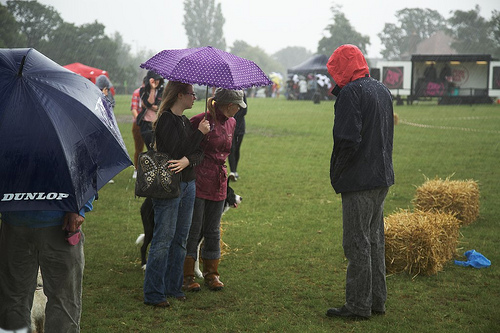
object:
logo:
[1, 191, 67, 202]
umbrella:
[0, 47, 133, 217]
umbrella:
[140, 46, 275, 132]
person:
[326, 44, 394, 318]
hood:
[326, 44, 370, 89]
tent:
[288, 54, 337, 101]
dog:
[135, 185, 242, 271]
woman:
[181, 86, 247, 292]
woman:
[144, 80, 209, 307]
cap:
[214, 88, 248, 108]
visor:
[239, 102, 247, 109]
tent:
[62, 62, 110, 84]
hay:
[383, 211, 464, 277]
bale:
[411, 169, 481, 226]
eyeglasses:
[179, 92, 196, 96]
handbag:
[134, 111, 189, 198]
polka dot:
[186, 78, 187, 79]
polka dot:
[189, 66, 191, 67]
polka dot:
[223, 78, 225, 80]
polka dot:
[208, 66, 213, 70]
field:
[80, 93, 499, 333]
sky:
[0, 0, 500, 58]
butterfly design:
[138, 153, 173, 194]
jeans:
[145, 181, 197, 305]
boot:
[182, 254, 200, 291]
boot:
[202, 258, 223, 290]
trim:
[201, 252, 220, 259]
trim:
[186, 253, 197, 260]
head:
[215, 87, 245, 118]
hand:
[198, 117, 211, 135]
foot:
[182, 279, 202, 292]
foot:
[205, 274, 225, 290]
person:
[297, 77, 307, 100]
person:
[306, 74, 317, 101]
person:
[292, 74, 299, 98]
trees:
[377, 4, 500, 61]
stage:
[413, 52, 489, 96]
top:
[155, 108, 207, 182]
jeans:
[0, 225, 85, 333]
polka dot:
[198, 74, 200, 77]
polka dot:
[208, 81, 210, 83]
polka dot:
[234, 81, 236, 83]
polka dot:
[223, 70, 225, 72]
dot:
[89, 71, 94, 75]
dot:
[102, 70, 106, 74]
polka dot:
[202, 57, 204, 59]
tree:
[182, 0, 227, 51]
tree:
[318, 1, 372, 59]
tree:
[0, 0, 135, 88]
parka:
[329, 73, 395, 195]